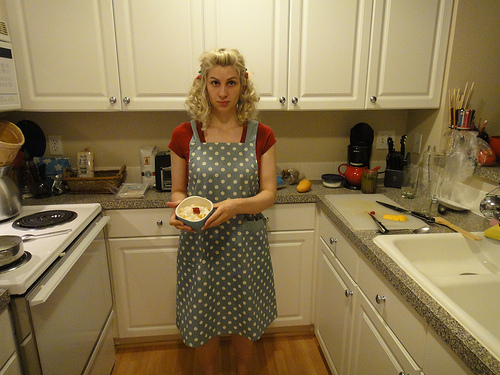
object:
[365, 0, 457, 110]
cabinet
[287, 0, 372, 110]
cabinet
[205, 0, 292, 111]
cabinet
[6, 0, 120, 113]
cabinet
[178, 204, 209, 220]
food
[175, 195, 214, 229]
bowl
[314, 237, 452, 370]
drawers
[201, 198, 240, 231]
hands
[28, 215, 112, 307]
handle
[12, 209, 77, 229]
black burner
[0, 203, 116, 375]
stove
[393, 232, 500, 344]
sink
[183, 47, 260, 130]
blonde hair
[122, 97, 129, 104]
knob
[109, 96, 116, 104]
knob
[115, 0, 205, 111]
cabinet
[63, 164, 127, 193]
basket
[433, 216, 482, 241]
spoon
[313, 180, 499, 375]
counter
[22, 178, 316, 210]
counter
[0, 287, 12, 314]
counter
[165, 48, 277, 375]
blond woman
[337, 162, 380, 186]
tea kettle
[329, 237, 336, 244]
knob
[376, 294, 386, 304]
knob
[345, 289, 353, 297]
knob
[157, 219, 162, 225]
knob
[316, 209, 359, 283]
drawer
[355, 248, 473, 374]
drawer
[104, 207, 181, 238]
drawer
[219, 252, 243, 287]
dots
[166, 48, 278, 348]
head phones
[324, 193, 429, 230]
cutting board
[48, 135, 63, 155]
outlet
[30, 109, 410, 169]
wall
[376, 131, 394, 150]
outlet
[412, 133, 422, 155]
outlet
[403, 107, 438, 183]
wall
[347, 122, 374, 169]
coffee maker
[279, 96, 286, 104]
metal knobs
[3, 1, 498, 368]
kitchen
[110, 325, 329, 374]
floor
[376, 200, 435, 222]
knife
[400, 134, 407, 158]
knife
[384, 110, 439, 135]
corner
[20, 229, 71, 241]
spoon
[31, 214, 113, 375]
door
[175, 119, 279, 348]
apron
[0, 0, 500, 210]
background